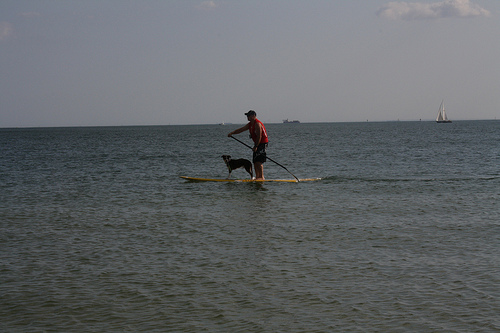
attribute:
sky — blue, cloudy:
[337, 23, 385, 40]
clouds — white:
[382, 0, 453, 37]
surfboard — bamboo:
[184, 172, 424, 184]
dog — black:
[214, 145, 262, 187]